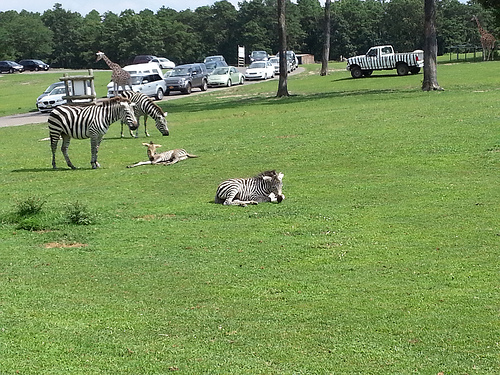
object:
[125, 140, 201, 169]
zebras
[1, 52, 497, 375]
field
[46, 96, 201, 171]
old and young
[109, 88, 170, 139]
zebra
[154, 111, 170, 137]
head down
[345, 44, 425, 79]
truck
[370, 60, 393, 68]
zebra paint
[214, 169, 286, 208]
zebra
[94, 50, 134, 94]
giraffe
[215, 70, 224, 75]
tourists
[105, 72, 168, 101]
cars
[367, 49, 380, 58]
staff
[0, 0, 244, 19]
sky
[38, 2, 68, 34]
trees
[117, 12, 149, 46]
leaves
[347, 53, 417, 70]
stripes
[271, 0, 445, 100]
three trees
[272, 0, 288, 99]
trunks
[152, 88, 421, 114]
shadows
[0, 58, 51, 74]
two cars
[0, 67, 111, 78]
parking lot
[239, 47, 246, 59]
sign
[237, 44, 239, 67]
post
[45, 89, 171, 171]
two zebras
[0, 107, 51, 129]
road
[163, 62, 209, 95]
car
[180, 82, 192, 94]
wheel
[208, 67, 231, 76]
front glass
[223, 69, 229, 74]
wiper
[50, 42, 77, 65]
branches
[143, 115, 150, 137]
leg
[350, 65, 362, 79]
wheel